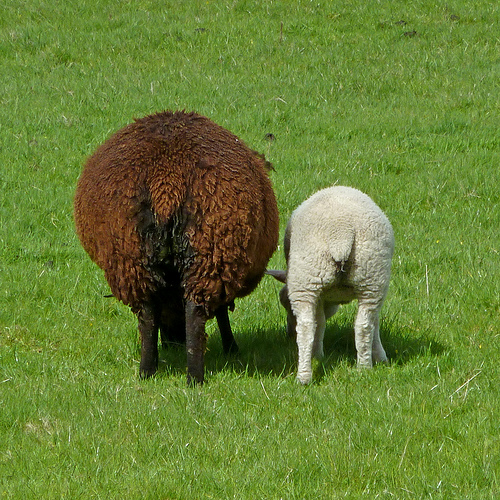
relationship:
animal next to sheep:
[74, 107, 278, 387] [273, 179, 420, 384]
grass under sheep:
[7, 1, 494, 494] [273, 179, 420, 384]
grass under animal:
[7, 1, 494, 494] [74, 107, 278, 387]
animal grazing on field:
[264, 183, 395, 386] [1, 0, 497, 499]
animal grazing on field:
[74, 107, 278, 387] [1, 0, 497, 499]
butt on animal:
[75, 106, 277, 307] [74, 107, 278, 387]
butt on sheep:
[288, 180, 395, 295] [273, 171, 398, 378]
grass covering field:
[7, 1, 494, 494] [1, 0, 497, 499]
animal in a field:
[264, 183, 395, 386] [18, 11, 486, 99]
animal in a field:
[74, 107, 278, 387] [18, 11, 486, 99]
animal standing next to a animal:
[264, 183, 395, 386] [74, 107, 278, 387]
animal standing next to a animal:
[74, 107, 278, 387] [264, 183, 395, 386]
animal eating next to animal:
[74, 107, 278, 387] [264, 183, 395, 386]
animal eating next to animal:
[264, 183, 395, 386] [74, 107, 278, 387]